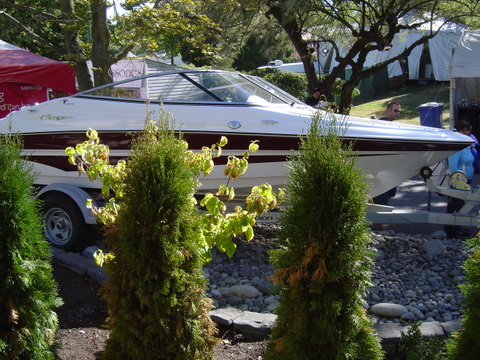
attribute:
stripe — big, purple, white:
[3, 131, 468, 150]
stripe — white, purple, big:
[9, 152, 399, 173]